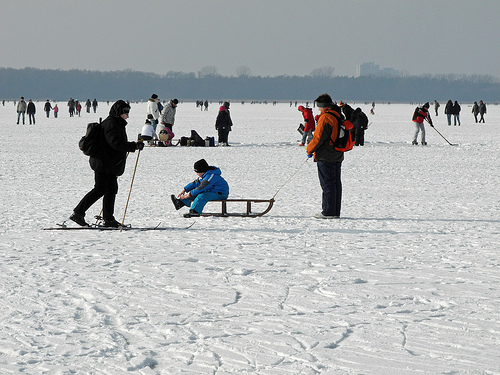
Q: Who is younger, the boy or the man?
A: The boy is younger than the man.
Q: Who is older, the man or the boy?
A: The man is older than the boy.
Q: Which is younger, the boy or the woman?
A: The boy is younger than the woman.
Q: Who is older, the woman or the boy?
A: The woman is older than the boy.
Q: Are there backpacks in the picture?
A: Yes, there is a backpack.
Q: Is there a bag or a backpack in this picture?
A: Yes, there is a backpack.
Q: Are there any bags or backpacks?
A: Yes, there is a backpack.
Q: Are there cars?
A: No, there are no cars.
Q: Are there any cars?
A: No, there are no cars.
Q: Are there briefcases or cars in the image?
A: No, there are no cars or briefcases.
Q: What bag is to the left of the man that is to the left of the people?
A: The bag is a backpack.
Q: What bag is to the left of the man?
A: The bag is a backpack.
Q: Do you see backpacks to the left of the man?
A: Yes, there is a backpack to the left of the man.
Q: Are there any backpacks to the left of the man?
A: Yes, there is a backpack to the left of the man.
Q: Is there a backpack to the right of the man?
A: No, the backpack is to the left of the man.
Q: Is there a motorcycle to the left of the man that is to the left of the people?
A: No, there is a backpack to the left of the man.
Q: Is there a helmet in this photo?
A: No, there are no helmets.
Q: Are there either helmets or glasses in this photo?
A: No, there are no helmets or glasses.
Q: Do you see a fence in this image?
A: No, there are no fences.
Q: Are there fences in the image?
A: No, there are no fences.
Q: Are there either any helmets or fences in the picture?
A: No, there are no fences or helmets.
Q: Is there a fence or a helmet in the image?
A: No, there are no fences or helmets.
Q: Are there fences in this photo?
A: No, there are no fences.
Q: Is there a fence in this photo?
A: No, there are no fences.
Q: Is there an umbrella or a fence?
A: No, there are no fences or umbrellas.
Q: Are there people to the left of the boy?
A: Yes, there are people to the left of the boy.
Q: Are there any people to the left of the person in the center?
A: Yes, there are people to the left of the boy.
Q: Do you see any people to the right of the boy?
A: No, the people are to the left of the boy.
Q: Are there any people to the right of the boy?
A: No, the people are to the left of the boy.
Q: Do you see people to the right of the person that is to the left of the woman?
A: No, the people are to the left of the boy.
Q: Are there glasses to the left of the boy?
A: No, there are people to the left of the boy.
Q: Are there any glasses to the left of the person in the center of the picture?
A: No, there are people to the left of the boy.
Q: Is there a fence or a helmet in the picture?
A: No, there are no fences or helmets.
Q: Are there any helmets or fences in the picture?
A: No, there are no fences or helmets.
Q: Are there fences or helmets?
A: No, there are no fences or helmets.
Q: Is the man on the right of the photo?
A: Yes, the man is on the right of the image.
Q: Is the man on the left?
A: No, the man is on the right of the image.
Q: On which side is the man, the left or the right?
A: The man is on the right of the image.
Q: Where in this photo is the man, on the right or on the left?
A: The man is on the right of the image.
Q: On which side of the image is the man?
A: The man is on the right of the image.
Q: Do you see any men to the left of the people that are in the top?
A: Yes, there is a man to the left of the people.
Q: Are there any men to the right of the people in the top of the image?
A: No, the man is to the left of the people.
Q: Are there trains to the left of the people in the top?
A: No, there is a man to the left of the people.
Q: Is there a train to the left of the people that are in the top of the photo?
A: No, there is a man to the left of the people.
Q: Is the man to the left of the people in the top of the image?
A: Yes, the man is to the left of the people.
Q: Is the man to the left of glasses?
A: No, the man is to the left of the people.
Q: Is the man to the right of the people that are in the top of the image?
A: No, the man is to the left of the people.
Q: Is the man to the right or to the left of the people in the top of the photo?
A: The man is to the left of the people.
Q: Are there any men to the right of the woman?
A: Yes, there is a man to the right of the woman.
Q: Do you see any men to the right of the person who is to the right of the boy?
A: Yes, there is a man to the right of the woman.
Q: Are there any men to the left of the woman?
A: No, the man is to the right of the woman.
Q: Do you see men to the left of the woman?
A: No, the man is to the right of the woman.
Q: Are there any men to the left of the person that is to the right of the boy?
A: No, the man is to the right of the woman.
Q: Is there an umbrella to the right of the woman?
A: No, there is a man to the right of the woman.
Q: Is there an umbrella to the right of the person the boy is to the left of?
A: No, there is a man to the right of the woman.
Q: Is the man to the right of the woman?
A: Yes, the man is to the right of the woman.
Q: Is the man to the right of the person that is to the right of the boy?
A: Yes, the man is to the right of the woman.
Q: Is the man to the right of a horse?
A: No, the man is to the right of the woman.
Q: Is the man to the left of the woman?
A: No, the man is to the right of the woman.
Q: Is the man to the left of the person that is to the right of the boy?
A: No, the man is to the right of the woman.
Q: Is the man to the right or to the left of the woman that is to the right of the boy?
A: The man is to the right of the woman.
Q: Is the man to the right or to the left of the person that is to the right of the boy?
A: The man is to the right of the woman.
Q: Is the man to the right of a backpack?
A: Yes, the man is to the right of a backpack.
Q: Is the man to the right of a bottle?
A: No, the man is to the right of a backpack.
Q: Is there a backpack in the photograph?
A: Yes, there is a backpack.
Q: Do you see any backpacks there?
A: Yes, there is a backpack.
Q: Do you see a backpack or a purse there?
A: Yes, there is a backpack.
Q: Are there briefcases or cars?
A: No, there are no cars or briefcases.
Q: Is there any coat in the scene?
A: Yes, there is a coat.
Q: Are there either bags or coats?
A: Yes, there is a coat.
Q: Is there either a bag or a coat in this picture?
A: Yes, there is a coat.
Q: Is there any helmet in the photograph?
A: No, there are no helmets.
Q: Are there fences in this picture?
A: No, there are no fences.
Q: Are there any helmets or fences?
A: No, there are no fences or helmets.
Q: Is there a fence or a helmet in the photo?
A: No, there are no fences or helmets.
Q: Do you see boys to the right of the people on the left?
A: Yes, there is a boy to the right of the people.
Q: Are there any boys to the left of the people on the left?
A: No, the boy is to the right of the people.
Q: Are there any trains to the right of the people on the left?
A: No, there is a boy to the right of the people.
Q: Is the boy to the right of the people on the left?
A: Yes, the boy is to the right of the people.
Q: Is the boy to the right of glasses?
A: No, the boy is to the right of the people.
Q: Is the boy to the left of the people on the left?
A: No, the boy is to the right of the people.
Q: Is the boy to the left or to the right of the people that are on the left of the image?
A: The boy is to the right of the people.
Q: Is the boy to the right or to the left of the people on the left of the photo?
A: The boy is to the right of the people.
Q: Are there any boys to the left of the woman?
A: Yes, there is a boy to the left of the woman.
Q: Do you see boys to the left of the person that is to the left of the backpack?
A: Yes, there is a boy to the left of the woman.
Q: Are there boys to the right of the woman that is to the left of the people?
A: No, the boy is to the left of the woman.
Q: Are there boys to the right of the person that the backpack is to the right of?
A: No, the boy is to the left of the woman.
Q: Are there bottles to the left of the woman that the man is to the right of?
A: No, there is a boy to the left of the woman.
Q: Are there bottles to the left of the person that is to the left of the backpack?
A: No, there is a boy to the left of the woman.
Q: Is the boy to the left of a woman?
A: Yes, the boy is to the left of a woman.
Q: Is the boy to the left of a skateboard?
A: No, the boy is to the left of a woman.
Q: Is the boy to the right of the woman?
A: No, the boy is to the left of the woman.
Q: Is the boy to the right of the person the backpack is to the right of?
A: No, the boy is to the left of the woman.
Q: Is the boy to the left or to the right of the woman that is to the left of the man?
A: The boy is to the left of the woman.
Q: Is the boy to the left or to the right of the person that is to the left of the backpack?
A: The boy is to the left of the woman.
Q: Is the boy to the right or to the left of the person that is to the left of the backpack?
A: The boy is to the left of the woman.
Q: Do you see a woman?
A: Yes, there is a woman.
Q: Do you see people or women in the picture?
A: Yes, there is a woman.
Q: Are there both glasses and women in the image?
A: No, there is a woman but no glasses.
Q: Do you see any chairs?
A: No, there are no chairs.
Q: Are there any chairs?
A: No, there are no chairs.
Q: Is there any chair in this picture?
A: No, there are no chairs.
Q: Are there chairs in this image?
A: No, there are no chairs.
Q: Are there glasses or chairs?
A: No, there are no chairs or glasses.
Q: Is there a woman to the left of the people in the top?
A: Yes, there is a woman to the left of the people.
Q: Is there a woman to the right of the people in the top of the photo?
A: No, the woman is to the left of the people.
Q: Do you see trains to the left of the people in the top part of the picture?
A: No, there is a woman to the left of the people.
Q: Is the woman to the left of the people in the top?
A: Yes, the woman is to the left of the people.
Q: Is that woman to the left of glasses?
A: No, the woman is to the left of the people.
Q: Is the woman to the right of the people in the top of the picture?
A: No, the woman is to the left of the people.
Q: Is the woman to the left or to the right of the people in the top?
A: The woman is to the left of the people.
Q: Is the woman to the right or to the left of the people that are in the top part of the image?
A: The woman is to the left of the people.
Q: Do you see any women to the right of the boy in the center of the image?
A: Yes, there is a woman to the right of the boy.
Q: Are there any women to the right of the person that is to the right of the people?
A: Yes, there is a woman to the right of the boy.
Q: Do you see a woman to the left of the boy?
A: No, the woman is to the right of the boy.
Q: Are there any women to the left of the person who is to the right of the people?
A: No, the woman is to the right of the boy.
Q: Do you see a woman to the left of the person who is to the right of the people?
A: No, the woman is to the right of the boy.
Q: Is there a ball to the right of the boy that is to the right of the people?
A: No, there is a woman to the right of the boy.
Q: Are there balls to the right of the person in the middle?
A: No, there is a woman to the right of the boy.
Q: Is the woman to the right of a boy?
A: Yes, the woman is to the right of a boy.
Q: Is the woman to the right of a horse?
A: No, the woman is to the right of a boy.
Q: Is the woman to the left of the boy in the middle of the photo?
A: No, the woman is to the right of the boy.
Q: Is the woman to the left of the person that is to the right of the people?
A: No, the woman is to the right of the boy.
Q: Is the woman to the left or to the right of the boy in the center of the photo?
A: The woman is to the right of the boy.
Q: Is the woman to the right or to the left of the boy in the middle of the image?
A: The woman is to the right of the boy.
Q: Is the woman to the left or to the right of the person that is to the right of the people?
A: The woman is to the right of the boy.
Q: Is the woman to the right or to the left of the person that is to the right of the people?
A: The woman is to the right of the boy.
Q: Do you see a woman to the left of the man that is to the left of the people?
A: Yes, there is a woman to the left of the man.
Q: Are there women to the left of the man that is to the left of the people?
A: Yes, there is a woman to the left of the man.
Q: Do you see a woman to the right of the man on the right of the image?
A: No, the woman is to the left of the man.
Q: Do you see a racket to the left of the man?
A: No, there is a woman to the left of the man.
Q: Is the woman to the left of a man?
A: Yes, the woman is to the left of a man.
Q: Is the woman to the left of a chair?
A: No, the woman is to the left of a man.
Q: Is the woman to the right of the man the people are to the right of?
A: No, the woman is to the left of the man.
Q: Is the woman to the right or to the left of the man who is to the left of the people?
A: The woman is to the left of the man.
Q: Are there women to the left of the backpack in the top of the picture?
A: Yes, there is a woman to the left of the backpack.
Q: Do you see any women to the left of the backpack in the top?
A: Yes, there is a woman to the left of the backpack.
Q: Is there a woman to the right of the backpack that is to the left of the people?
A: No, the woman is to the left of the backpack.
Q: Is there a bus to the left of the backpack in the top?
A: No, there is a woman to the left of the backpack.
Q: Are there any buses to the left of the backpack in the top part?
A: No, there is a woman to the left of the backpack.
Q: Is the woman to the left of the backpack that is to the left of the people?
A: Yes, the woman is to the left of the backpack.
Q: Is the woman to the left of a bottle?
A: No, the woman is to the left of the backpack.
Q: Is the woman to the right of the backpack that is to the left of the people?
A: No, the woman is to the left of the backpack.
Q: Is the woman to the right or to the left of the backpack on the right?
A: The woman is to the left of the backpack.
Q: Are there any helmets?
A: No, there are no helmets.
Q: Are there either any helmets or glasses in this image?
A: No, there are no helmets or glasses.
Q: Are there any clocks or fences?
A: No, there are no fences or clocks.